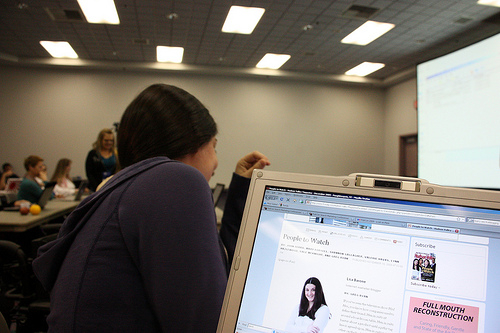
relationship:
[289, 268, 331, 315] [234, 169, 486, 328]
woman on computer screen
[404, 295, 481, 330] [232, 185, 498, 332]
advertisement on screen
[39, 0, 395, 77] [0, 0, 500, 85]
lights on ceiling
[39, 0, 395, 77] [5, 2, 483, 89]
lights on ceiling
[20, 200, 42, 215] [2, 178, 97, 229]
fruit on table top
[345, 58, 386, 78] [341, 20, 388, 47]
lights overhead lights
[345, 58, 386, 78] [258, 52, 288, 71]
lights overhead lights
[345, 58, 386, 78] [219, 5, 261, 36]
lights overhead lights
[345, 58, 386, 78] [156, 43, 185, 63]
lights overhead lights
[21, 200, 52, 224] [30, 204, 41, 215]
fruit and apple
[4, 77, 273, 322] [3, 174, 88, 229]
people sitting desks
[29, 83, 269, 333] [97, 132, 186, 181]
people with hair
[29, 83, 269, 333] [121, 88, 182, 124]
people with hair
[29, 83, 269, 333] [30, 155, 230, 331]
people wearing a hoodie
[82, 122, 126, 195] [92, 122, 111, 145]
woman has blonde hair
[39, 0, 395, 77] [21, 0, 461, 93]
lights on ceiling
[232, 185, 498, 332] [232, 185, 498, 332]
screen on screen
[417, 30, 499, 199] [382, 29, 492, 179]
projector on wall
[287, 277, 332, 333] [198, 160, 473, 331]
woman on screen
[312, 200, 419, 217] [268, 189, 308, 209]
box on browser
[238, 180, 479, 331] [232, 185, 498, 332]
web page on screen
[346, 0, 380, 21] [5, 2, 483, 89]
vent on ceiling